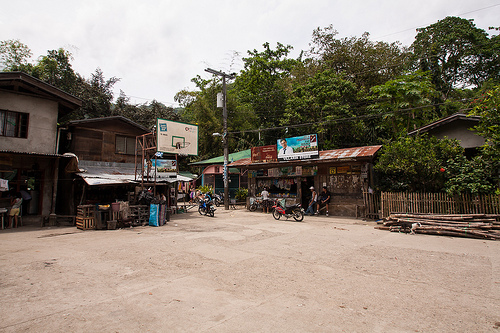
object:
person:
[7, 193, 22, 229]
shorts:
[9, 208, 20, 216]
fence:
[376, 188, 498, 235]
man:
[260, 188, 271, 214]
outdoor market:
[247, 166, 316, 212]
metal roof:
[318, 145, 383, 160]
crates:
[76, 204, 98, 231]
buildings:
[0, 60, 498, 242]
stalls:
[2, 76, 497, 247]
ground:
[368, 65, 392, 105]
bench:
[304, 203, 353, 216]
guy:
[314, 186, 330, 216]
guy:
[304, 186, 318, 216]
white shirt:
[157, 119, 199, 156]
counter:
[246, 189, 295, 200]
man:
[202, 191, 216, 214]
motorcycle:
[271, 197, 306, 221]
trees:
[1, 14, 500, 194]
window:
[0, 109, 28, 138]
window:
[113, 134, 143, 155]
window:
[240, 169, 249, 190]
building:
[1, 71, 83, 232]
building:
[185, 149, 251, 198]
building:
[402, 109, 499, 164]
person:
[278, 138, 293, 154]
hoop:
[130, 133, 152, 229]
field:
[2, 221, 497, 331]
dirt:
[2, 236, 60, 331]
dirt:
[57, 233, 189, 331]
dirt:
[215, 211, 271, 219]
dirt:
[297, 250, 464, 328]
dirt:
[390, 232, 497, 257]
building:
[63, 112, 175, 232]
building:
[225, 145, 384, 222]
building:
[177, 171, 198, 200]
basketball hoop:
[175, 142, 191, 150]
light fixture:
[217, 92, 225, 107]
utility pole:
[222, 77, 229, 210]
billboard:
[277, 134, 319, 159]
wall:
[333, 173, 357, 198]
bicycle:
[198, 201, 217, 217]